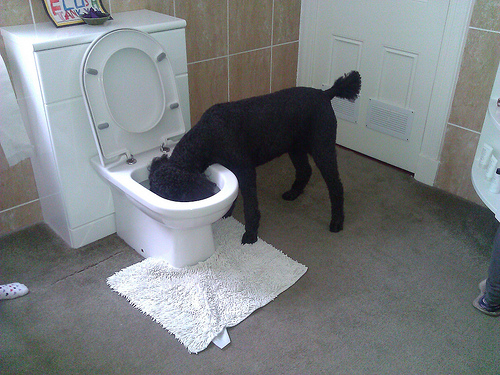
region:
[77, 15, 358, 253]
black dog drinking out of toilet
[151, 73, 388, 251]
black dog with head in toilet bowl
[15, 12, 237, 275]
white toilet bowl and tank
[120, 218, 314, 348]
white rug around toilet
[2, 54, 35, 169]
white toilet paper hanging from roll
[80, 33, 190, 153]
raised seat of white toilet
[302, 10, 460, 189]
white closed door of bathroom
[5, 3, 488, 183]
biege colored tiles on walls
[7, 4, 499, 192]
white grout between white tiles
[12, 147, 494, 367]
gray floor in bathroom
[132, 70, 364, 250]
black dog drinking out of white toilet bowl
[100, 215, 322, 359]
white rug around base of toilet bowl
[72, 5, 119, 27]
glass bowl on top of toilet tank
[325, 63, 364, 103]
short tail of black dog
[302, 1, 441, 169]
white door to bathroom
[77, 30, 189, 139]
underside of toilet seat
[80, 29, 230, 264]
toilet bowl with seat up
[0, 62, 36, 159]
toilet paper hanging off roll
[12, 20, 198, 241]
toilet tank of white toilet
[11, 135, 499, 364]
gray flooring of bathroom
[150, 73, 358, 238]
black poodle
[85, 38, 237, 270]
white toilet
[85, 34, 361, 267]
black poodle drinking out of a toilet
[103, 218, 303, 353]
white mat in front of the toilet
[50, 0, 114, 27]
children's art above the toilet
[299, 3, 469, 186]
white bathroom door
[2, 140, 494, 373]
green-gray carpet on the bathroom floor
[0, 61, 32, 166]
roll of toilet paper next to the toilet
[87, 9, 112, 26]
bowl of potpourri above the toilet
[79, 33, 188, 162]
toilet seat in the upright position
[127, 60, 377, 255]
a dog drinking water from a toilet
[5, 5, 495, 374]
a dog is in a bathroom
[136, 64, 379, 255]
a black dog in a bathroom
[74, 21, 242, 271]
lid of toilet is open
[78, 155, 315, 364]
a white rug in front a toilet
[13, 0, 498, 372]
door of bathroom is white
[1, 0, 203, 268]
a white box behind a toilet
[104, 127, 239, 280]
head of dog inside a toilet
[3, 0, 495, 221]
wall of bathroom is brown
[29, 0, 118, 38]
a book over a white surface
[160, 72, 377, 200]
dog drinks from toilet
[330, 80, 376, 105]
dog has short black tail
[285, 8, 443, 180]
white door behind dog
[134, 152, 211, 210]
dog has curly ears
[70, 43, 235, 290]
dog has head in white toilet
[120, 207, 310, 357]
white rug under toilet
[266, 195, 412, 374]
dog is on grey floor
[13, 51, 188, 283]
white cabinet behind toilet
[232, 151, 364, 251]
dog has black legs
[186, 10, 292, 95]
tan wall behind toilet and cabinet